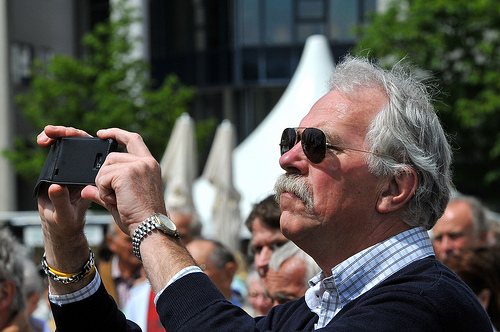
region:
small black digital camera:
[27, 124, 120, 204]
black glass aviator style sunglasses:
[272, 123, 334, 169]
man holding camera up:
[30, 48, 499, 330]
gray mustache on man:
[266, 171, 326, 213]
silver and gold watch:
[126, 210, 182, 252]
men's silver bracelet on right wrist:
[38, 248, 97, 288]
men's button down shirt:
[280, 225, 453, 329]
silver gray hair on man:
[327, 53, 467, 243]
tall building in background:
[2, 4, 497, 192]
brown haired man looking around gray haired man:
[235, 191, 305, 281]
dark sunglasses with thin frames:
[277, 123, 421, 175]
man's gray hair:
[329, 31, 456, 230]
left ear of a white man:
[373, 162, 420, 217]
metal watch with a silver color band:
[128, 209, 185, 260]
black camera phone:
[28, 118, 118, 200]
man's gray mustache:
[273, 169, 321, 217]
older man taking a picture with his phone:
[1, 42, 497, 330]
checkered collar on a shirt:
[330, 221, 442, 307]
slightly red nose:
[277, 141, 313, 176]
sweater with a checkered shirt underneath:
[39, 222, 499, 330]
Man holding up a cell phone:
[33, 55, 494, 330]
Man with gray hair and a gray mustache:
[272, 52, 451, 255]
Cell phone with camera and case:
[32, 134, 116, 193]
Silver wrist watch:
[128, 210, 181, 259]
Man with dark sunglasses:
[272, 54, 453, 239]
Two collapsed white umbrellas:
[161, 111, 246, 259]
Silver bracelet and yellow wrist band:
[39, 246, 97, 288]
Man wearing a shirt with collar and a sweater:
[30, 52, 495, 329]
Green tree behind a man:
[346, 4, 495, 201]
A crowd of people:
[0, 65, 495, 327]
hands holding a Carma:
[17, 118, 201, 208]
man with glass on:
[260, 49, 450, 263]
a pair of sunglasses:
[268, 119, 420, 184]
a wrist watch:
[135, 212, 177, 268]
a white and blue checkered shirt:
[297, 234, 434, 309]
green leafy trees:
[29, 20, 184, 120]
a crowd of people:
[226, 209, 306, 289]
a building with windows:
[152, 0, 382, 80]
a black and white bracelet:
[31, 249, 99, 290]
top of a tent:
[244, 44, 391, 131]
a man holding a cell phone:
[20, 59, 477, 329]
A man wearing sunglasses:
[271, 115, 358, 178]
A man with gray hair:
[326, 60, 471, 227]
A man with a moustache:
[266, 171, 320, 220]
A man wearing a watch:
[125, 206, 182, 261]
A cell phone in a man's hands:
[32, 125, 138, 200]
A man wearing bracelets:
[28, 246, 111, 288]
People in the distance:
[137, 191, 322, 327]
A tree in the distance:
[32, 8, 192, 158]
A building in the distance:
[157, 1, 319, 130]